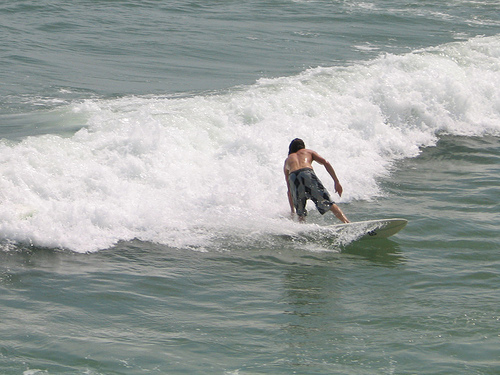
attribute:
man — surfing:
[281, 135, 348, 232]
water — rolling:
[20, 8, 378, 59]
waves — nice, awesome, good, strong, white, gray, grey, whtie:
[11, 53, 485, 122]